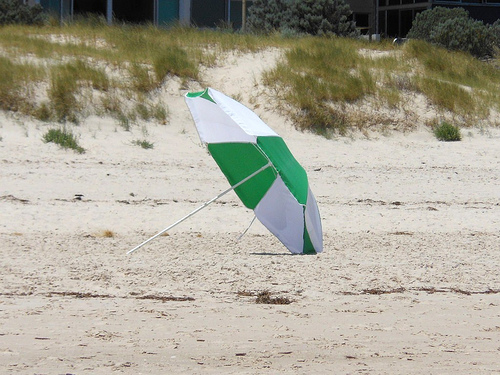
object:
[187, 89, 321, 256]
umbrella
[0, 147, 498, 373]
beach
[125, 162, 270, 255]
pole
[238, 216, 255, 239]
strap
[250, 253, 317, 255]
shadow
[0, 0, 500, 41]
building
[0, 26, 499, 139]
sand hill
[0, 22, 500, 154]
grass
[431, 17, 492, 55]
shrub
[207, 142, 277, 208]
panel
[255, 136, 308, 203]
panel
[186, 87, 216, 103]
panel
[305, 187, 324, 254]
panel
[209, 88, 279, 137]
panel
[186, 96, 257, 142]
panel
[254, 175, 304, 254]
panel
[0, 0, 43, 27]
tree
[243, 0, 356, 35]
tree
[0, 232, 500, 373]
sand